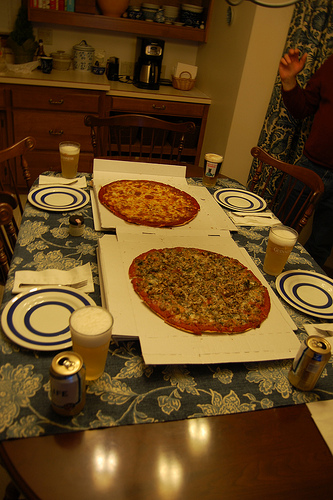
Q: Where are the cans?
A: On the table.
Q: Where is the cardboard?
A: Under the pizza.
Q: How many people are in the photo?
A: 1.